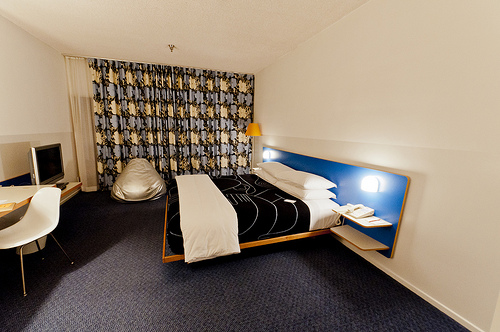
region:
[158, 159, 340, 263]
bed attached to wall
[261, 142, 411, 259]
blue headboard attached to wall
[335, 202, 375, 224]
phone next to bed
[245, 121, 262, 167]
lamp next to bed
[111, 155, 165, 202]
silver bean bag chair on floor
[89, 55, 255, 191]
dark-colored curtain over window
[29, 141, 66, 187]
television against wall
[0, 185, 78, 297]
a white plastic chair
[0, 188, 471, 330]
a dark-colored carpet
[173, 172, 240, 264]
a white blanket on the bed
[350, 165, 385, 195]
A wall mounted light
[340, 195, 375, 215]
A white wall phone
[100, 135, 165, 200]
A silver bean bag chair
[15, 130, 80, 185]
A small flat screen tv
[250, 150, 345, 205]
Two stacks of small white pillows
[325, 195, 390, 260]
Two wall mounted shelving areas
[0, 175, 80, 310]
A rounded white chair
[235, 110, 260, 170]
An orange floor lamp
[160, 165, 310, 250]
A black/white blanket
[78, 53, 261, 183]
A blue/yellow decorative curtain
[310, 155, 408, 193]
part of a blue headboard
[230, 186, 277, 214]
black and white comforter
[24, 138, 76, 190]
computer monitor on stand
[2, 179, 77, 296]
white chair next to desk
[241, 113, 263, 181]
orange lamp shade on pole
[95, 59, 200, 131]
colorful curtains on window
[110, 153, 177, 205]
silver bean bag chair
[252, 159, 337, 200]
four white pillows on the bed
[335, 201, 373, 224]
phone on the shelf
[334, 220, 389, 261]
shelves on the headboard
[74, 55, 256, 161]
a curtain on a window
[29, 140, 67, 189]
a computer monitor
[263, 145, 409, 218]
a blue headboard of a bed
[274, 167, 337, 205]
two pillows on a bed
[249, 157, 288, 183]
two pillows on a bed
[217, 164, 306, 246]
a black and white striped bedspread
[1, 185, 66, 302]
a white desk chair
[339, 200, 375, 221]
a white telephone on a self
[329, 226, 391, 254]
an empty shelf on the wall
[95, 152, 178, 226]
a black chair with a white pillow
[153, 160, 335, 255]
the bed is made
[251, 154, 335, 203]
pillows on the bed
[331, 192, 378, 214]
telephone beside the bed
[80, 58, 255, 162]
the curtain is drawn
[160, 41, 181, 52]
the sprinkler on the ceiling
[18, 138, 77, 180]
the television is off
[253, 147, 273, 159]
light on the headboard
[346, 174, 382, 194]
light on the headboard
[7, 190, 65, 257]
the white chair is empty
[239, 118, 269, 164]
the lamp beside bed